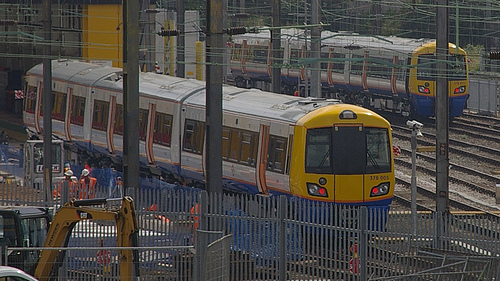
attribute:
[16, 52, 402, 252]
train — commuter, grey, yellow, white, blue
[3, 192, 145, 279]
excavator — yellow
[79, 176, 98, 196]
vest — orange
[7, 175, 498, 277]
fence — blue, metal, grey, portable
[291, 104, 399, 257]
front — yellow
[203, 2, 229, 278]
bar — gray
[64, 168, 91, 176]
hard hats — white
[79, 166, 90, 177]
hat — white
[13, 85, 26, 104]
sign — red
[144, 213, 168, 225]
safety vest — orange